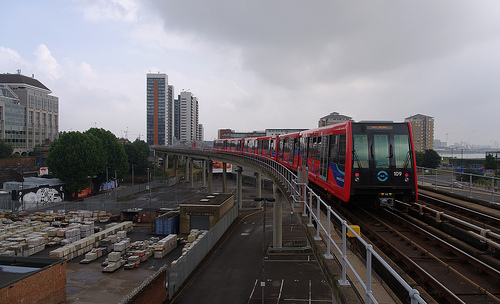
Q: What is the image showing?
A: It is showing a street.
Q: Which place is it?
A: It is a street.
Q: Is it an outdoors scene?
A: Yes, it is outdoors.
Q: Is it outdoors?
A: Yes, it is outdoors.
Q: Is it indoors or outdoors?
A: It is outdoors.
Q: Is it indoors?
A: No, it is outdoors.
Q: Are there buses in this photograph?
A: No, there are no buses.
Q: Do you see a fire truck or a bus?
A: No, there are no buses or fire trucks.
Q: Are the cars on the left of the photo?
A: Yes, the cars are on the left of the image.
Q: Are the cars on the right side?
A: No, the cars are on the left of the image.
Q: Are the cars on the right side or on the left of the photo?
A: The cars are on the left of the image.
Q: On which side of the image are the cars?
A: The cars are on the left of the image.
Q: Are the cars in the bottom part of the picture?
A: Yes, the cars are in the bottom of the image.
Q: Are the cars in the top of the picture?
A: No, the cars are in the bottom of the image.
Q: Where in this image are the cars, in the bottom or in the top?
A: The cars are in the bottom of the image.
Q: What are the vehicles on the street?
A: The vehicles are cars.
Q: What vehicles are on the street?
A: The vehicles are cars.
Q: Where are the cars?
A: The cars are on the street.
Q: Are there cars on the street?
A: Yes, there are cars on the street.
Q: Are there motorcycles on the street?
A: No, there are cars on the street.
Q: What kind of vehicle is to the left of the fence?
A: The vehicles are cars.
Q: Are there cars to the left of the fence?
A: Yes, there are cars to the left of the fence.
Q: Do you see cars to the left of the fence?
A: Yes, there are cars to the left of the fence.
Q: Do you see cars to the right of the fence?
A: No, the cars are to the left of the fence.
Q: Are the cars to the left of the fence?
A: Yes, the cars are to the left of the fence.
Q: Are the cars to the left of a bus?
A: No, the cars are to the left of the fence.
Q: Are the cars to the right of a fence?
A: No, the cars are to the left of a fence.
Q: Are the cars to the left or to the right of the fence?
A: The cars are to the left of the fence.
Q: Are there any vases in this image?
A: No, there are no vases.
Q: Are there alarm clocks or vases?
A: No, there are no vases or alarm clocks.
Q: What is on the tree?
A: The leaves are on the tree.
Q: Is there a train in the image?
A: Yes, there is a train.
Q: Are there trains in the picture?
A: Yes, there is a train.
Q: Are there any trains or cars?
A: Yes, there is a train.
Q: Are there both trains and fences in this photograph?
A: Yes, there are both a train and a fence.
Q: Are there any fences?
A: Yes, there is a fence.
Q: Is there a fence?
A: Yes, there is a fence.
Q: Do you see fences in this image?
A: Yes, there is a fence.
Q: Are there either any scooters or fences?
A: Yes, there is a fence.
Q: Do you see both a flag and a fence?
A: No, there is a fence but no flags.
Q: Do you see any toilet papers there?
A: No, there are no toilet papers.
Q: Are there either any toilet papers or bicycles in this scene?
A: No, there are no toilet papers or bicycles.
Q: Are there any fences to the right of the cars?
A: Yes, there is a fence to the right of the cars.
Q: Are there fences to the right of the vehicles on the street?
A: Yes, there is a fence to the right of the cars.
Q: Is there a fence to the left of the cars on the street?
A: No, the fence is to the right of the cars.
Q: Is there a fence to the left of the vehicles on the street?
A: No, the fence is to the right of the cars.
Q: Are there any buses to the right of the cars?
A: No, there is a fence to the right of the cars.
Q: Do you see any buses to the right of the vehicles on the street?
A: No, there is a fence to the right of the cars.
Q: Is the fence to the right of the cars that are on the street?
A: Yes, the fence is to the right of the cars.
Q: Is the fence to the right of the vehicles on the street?
A: Yes, the fence is to the right of the cars.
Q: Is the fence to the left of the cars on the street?
A: No, the fence is to the right of the cars.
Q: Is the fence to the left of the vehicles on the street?
A: No, the fence is to the right of the cars.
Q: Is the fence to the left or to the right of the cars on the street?
A: The fence is to the right of the cars.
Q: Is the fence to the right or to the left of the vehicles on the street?
A: The fence is to the right of the cars.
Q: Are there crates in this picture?
A: No, there are no crates.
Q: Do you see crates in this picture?
A: No, there are no crates.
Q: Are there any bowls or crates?
A: No, there are no crates or bowls.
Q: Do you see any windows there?
A: Yes, there is a window.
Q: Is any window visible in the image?
A: Yes, there is a window.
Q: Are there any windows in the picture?
A: Yes, there is a window.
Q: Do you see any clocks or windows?
A: Yes, there is a window.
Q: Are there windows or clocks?
A: Yes, there is a window.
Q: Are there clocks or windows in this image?
A: Yes, there is a window.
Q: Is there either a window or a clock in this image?
A: Yes, there is a window.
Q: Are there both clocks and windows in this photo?
A: No, there is a window but no clocks.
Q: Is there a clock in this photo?
A: No, there are no clocks.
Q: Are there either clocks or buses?
A: No, there are no clocks or buses.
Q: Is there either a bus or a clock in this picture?
A: No, there are no clocks or buses.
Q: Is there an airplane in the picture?
A: No, there are no airplanes.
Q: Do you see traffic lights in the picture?
A: No, there are no traffic lights.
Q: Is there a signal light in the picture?
A: No, there are no traffic lights.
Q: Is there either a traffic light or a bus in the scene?
A: No, there are no traffic lights or buses.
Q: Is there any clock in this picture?
A: No, there are no clocks.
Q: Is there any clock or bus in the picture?
A: No, there are no clocks or buses.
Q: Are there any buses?
A: No, there are no buses.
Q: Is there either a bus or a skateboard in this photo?
A: No, there are no buses or skateboards.